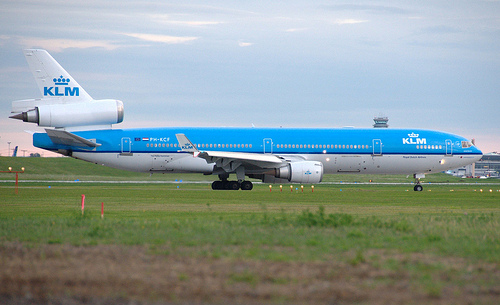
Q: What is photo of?
A: Jet ready for take off.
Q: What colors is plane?
A: Blue and white.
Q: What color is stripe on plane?
A: Dark blue.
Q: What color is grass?
A: Green and brown.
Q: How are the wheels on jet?
A: Down.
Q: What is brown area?
A: Dry surface.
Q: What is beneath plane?
A: Green grass.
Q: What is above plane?
A: Sky.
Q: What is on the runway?
A: An airplane.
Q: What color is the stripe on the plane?
A: Blue.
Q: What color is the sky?
A: Blue.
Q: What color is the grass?
A: Brown and green.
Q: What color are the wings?
A: White.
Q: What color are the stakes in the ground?
A: Orange.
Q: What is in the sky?
A: Clouds.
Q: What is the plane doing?
A: Getting ready to take off.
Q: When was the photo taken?
A: Daytime.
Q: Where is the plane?
A: On the runway.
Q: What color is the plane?
A: Blue and white.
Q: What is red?
A: The indicators.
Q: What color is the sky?
A: Blue.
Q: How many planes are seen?
A: 1.